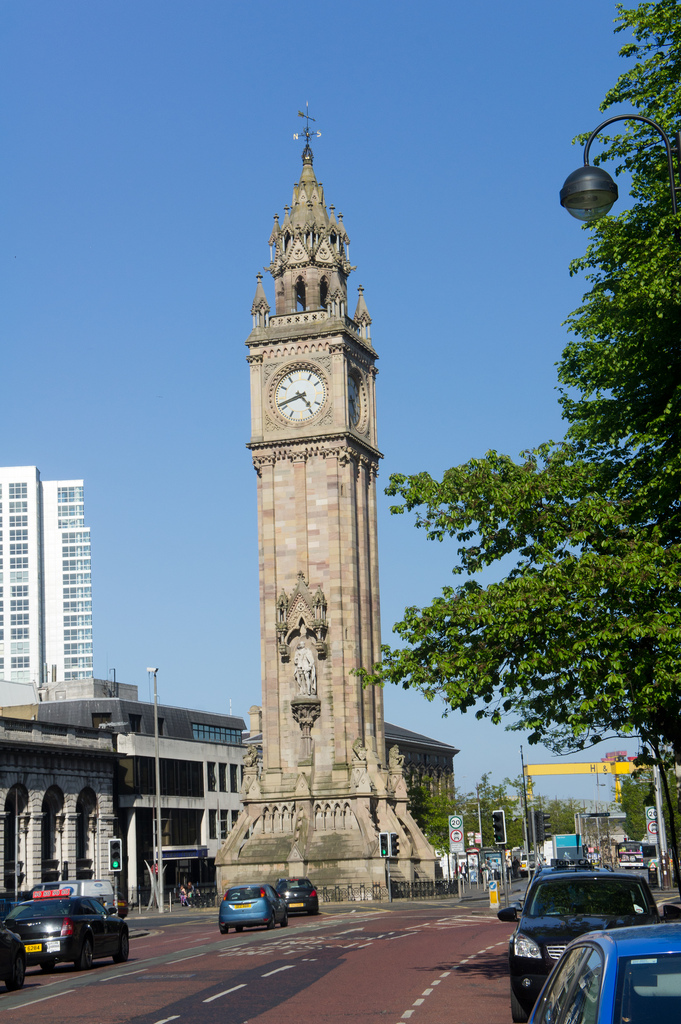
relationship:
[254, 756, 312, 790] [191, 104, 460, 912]
wall on side of building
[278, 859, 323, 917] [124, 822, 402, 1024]
car driving on road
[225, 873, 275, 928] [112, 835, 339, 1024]
car driving on road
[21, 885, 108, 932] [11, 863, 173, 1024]
car driving on road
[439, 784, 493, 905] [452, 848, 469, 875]
signs connected to gray pole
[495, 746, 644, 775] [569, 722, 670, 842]
sign attached to poles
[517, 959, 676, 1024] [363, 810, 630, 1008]
car driving on road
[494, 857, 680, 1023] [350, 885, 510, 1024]
car driving on road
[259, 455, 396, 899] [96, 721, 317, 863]
large clock tower near building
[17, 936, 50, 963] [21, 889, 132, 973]
plate attached to car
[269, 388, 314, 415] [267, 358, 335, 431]
hands are attached to clock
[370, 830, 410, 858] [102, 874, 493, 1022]
lights are hanging over street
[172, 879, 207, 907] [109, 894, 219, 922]
people are walking over sidewalk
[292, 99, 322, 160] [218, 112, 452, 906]
weather vane on top of clocktower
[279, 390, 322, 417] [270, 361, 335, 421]
hands are attached to clock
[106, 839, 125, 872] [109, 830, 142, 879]
light are attached to stoplight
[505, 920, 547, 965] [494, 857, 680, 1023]
headlight are attached to car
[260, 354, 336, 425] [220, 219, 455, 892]
clock are attached to tower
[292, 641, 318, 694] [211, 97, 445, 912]
statue on a building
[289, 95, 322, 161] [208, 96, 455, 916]
weather vane on a tower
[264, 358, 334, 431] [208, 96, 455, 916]
clock on tower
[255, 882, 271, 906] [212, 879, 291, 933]
red light on back of vehicle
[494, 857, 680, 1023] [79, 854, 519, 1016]
car parked on side of road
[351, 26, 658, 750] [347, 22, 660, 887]
leaves on tree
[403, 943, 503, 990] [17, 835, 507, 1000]
shadow on street